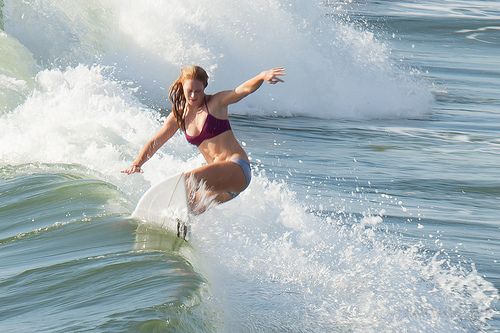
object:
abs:
[199, 140, 225, 163]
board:
[127, 172, 193, 248]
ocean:
[0, 2, 497, 330]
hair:
[169, 64, 209, 133]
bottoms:
[226, 159, 252, 199]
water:
[324, 57, 464, 194]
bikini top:
[181, 95, 232, 147]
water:
[33, 109, 134, 205]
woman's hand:
[121, 165, 145, 175]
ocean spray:
[1, 5, 445, 127]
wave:
[15, 63, 482, 331]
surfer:
[122, 64, 286, 240]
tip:
[158, 172, 189, 209]